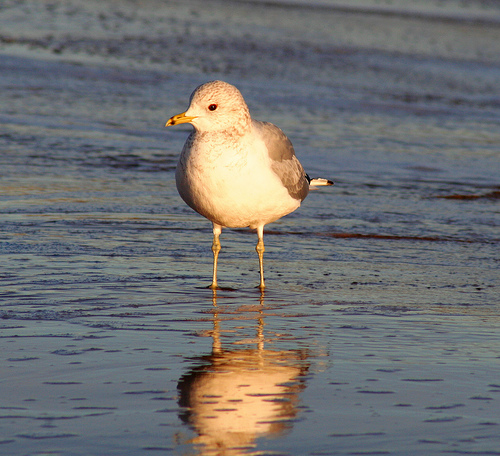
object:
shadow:
[175, 305, 312, 456]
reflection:
[176, 307, 312, 455]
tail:
[308, 177, 334, 187]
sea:
[5, 0, 497, 455]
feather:
[309, 177, 335, 184]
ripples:
[0, 242, 499, 454]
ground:
[0, 0, 500, 456]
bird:
[162, 80, 335, 290]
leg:
[253, 227, 267, 290]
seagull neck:
[193, 126, 256, 141]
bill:
[164, 113, 195, 127]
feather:
[222, 161, 257, 198]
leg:
[210, 220, 223, 292]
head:
[163, 78, 251, 134]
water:
[0, 0, 498, 453]